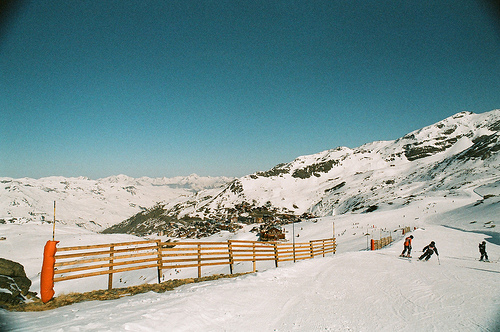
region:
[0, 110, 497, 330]
Mountain slope covered with snow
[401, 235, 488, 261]
Three skiers on snow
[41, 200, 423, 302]
Fence by the skiing slope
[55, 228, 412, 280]
Wooden slats of the fence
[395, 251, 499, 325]
Ski trails on snow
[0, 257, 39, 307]
A black rock the fence edge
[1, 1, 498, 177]
Dark blue sky above the snow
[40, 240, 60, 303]
Soft orange colored padding on the fence pole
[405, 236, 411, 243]
Red jacket on a skier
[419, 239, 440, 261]
A skier in motion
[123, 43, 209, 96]
blue sky above the land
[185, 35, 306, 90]
sky with no clouds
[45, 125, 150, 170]
light in the sky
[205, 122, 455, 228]
mountains on the ground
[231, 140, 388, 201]
snow on the mountains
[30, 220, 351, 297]
orange fence next to people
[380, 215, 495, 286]
three people in the snow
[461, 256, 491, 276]
shadow on the ground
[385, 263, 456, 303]
snow on the ground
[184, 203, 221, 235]
rock under the snow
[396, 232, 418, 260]
a person skiing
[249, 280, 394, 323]
the snow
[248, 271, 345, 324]
the snow is white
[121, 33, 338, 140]
the sky is clear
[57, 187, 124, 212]
the snow on the mountain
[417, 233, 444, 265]
a person skiing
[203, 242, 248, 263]
railing is orange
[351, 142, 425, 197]
the mountain is covered in snow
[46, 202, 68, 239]
a pole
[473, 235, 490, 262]
a person standing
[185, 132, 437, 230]
the mountain is covered with snow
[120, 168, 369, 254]
the mountain is covered with snow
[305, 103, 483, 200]
the mountain is covered with snow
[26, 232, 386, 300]
the fence is orange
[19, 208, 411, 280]
the fence is orange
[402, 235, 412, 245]
the skier is wearing a jacket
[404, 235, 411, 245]
the jacket is red in color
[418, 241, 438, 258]
the skier is going down the hill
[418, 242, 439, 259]
the skier is at an angle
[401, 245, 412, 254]
the skier is wearing long pants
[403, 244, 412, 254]
the pants are black in color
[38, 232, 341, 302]
a fence runs along the snow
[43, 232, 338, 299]
the fence is orange in color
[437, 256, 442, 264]
the skier is using a ski pole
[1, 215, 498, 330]
the ground is filled with snow